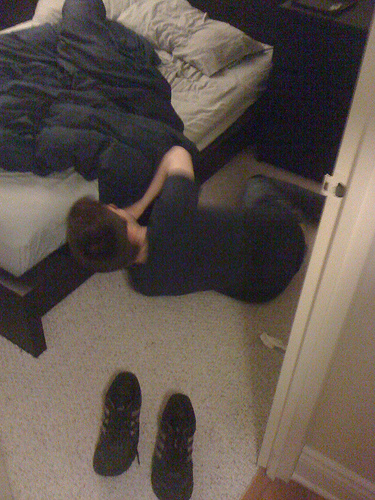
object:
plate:
[324, 176, 344, 209]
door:
[302, 273, 345, 330]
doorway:
[0, 2, 374, 494]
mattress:
[2, 0, 272, 276]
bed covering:
[0, 0, 280, 273]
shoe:
[147, 391, 212, 500]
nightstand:
[254, 0, 365, 180]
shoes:
[92, 367, 200, 500]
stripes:
[139, 422, 175, 463]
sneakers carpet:
[85, 372, 201, 500]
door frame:
[253, 0, 373, 500]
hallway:
[239, 440, 316, 500]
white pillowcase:
[118, 1, 263, 74]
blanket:
[0, 1, 201, 226]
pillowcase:
[185, 15, 261, 67]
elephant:
[257, 329, 288, 352]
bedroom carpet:
[0, 146, 324, 498]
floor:
[0, 144, 365, 495]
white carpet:
[0, 143, 322, 500]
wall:
[304, 233, 372, 486]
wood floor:
[260, 473, 320, 497]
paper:
[255, 330, 290, 354]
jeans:
[244, 172, 324, 239]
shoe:
[90, 367, 145, 480]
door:
[248, 0, 375, 500]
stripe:
[183, 434, 192, 458]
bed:
[0, 0, 272, 279]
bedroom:
[1, 0, 374, 498]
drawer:
[263, 67, 348, 141]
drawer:
[274, 17, 363, 87]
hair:
[63, 195, 140, 273]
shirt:
[125, 173, 307, 305]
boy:
[67, 146, 313, 332]